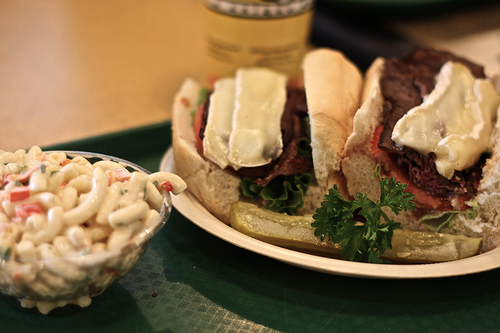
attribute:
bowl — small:
[0, 146, 175, 316]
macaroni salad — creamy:
[2, 144, 190, 316]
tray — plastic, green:
[0, 117, 499, 333]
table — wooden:
[1, 0, 321, 157]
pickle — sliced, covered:
[228, 196, 486, 267]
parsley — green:
[308, 162, 418, 267]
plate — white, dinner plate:
[155, 142, 500, 284]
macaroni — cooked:
[143, 169, 190, 196]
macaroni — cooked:
[104, 195, 153, 230]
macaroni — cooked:
[29, 161, 67, 195]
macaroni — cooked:
[20, 204, 67, 248]